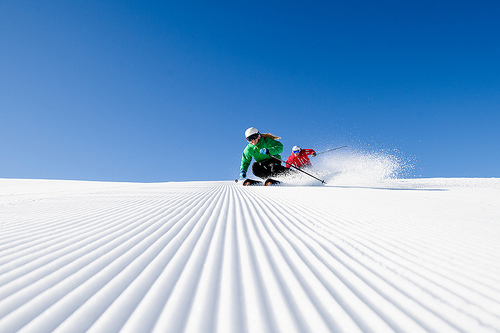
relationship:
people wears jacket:
[237, 125, 290, 179] [229, 127, 289, 184]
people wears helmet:
[237, 125, 290, 179] [241, 120, 263, 140]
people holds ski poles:
[237, 125, 290, 179] [277, 157, 330, 190]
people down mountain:
[241, 125, 311, 189] [237, 182, 404, 322]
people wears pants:
[237, 125, 290, 179] [250, 157, 290, 177]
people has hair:
[237, 125, 290, 179] [246, 122, 276, 141]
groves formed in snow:
[2, 178, 494, 332] [2, 180, 482, 331]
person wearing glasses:
[238, 125, 295, 176] [244, 130, 259, 142]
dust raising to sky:
[326, 144, 434, 195] [16, 20, 467, 150]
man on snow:
[283, 137, 333, 187] [2, 180, 482, 331]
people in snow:
[237, 125, 290, 179] [2, 180, 482, 331]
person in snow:
[283, 145, 316, 171] [2, 180, 482, 331]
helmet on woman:
[243, 126, 258, 138] [238, 125, 298, 179]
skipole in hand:
[255, 150, 327, 188] [260, 146, 270, 156]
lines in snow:
[137, 215, 257, 308] [2, 180, 482, 331]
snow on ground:
[47, 226, 348, 299] [1, 179, 482, 329]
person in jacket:
[283, 145, 316, 171] [286, 146, 318, 163]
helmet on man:
[290, 144, 300, 153] [285, 145, 317, 169]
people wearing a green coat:
[237, 125, 290, 179] [238, 135, 281, 174]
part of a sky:
[5, 71, 485, 200] [93, 22, 189, 114]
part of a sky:
[23, 105, 488, 190] [88, 21, 223, 146]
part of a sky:
[142, 77, 209, 180] [0, 4, 487, 156]